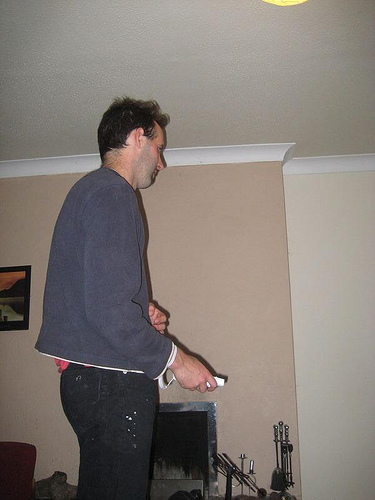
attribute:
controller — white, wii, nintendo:
[203, 354, 235, 412]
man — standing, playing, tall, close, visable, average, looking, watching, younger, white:
[67, 101, 192, 424]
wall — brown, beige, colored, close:
[184, 180, 280, 301]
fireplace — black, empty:
[166, 400, 228, 488]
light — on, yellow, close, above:
[260, 3, 324, 16]